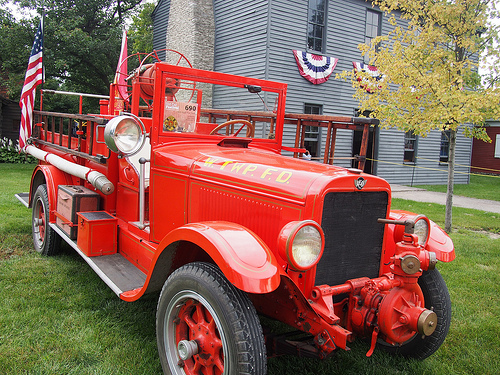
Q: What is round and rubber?
A: Tires.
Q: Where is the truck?
A: On the grass.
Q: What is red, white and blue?
A: A flag.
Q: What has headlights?
A: A truck.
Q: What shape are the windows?
A: Rectangular.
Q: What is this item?
A: Red fire truck.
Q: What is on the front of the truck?
A: Headlight.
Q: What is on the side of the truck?
A: Black tires.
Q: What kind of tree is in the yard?
A: Maple tree.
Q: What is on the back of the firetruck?
A: Flag.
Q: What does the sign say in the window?
A: 690.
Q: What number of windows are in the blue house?
A: 8.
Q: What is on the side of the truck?
A: Letters in yellow.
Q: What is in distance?
A: Trees in the distance.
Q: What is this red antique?
A: Fire truck.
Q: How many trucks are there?
A: One.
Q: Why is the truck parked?
A: It's not moving.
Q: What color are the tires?
A: Black.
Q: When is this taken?
A: During the daytime.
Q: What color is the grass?
A: Green.